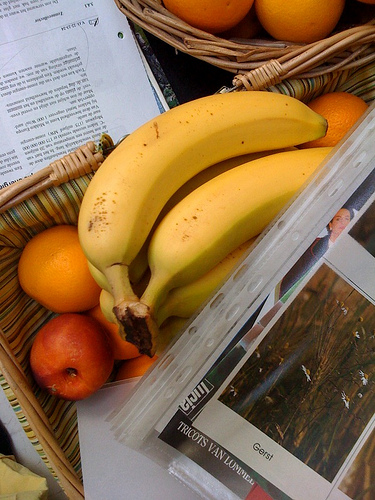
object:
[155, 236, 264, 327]
banana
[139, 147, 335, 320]
banana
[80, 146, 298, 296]
banana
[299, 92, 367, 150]
orange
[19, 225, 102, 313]
apricot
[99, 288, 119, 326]
bananas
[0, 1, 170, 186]
paper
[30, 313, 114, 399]
apple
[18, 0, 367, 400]
fruit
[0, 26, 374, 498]
basket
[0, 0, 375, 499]
cloth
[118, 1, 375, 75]
basket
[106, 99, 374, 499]
paper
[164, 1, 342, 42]
fruit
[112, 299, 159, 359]
stem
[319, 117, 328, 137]
end